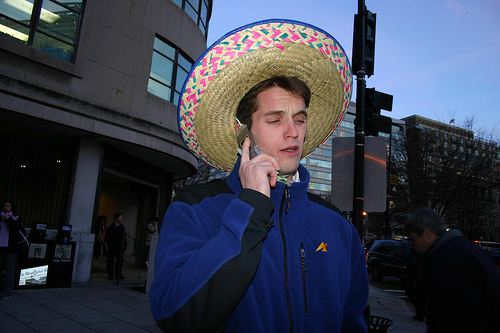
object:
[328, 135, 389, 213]
sign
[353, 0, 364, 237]
post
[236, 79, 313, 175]
man's head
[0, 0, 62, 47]
lights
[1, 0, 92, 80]
window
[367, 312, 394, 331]
bin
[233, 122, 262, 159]
cellphone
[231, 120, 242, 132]
ear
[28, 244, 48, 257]
papers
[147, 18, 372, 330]
man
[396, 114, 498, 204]
building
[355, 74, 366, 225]
sign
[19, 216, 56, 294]
newpaper bin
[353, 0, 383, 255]
traffic light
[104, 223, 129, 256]
jacket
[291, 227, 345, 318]
zipper pocket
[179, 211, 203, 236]
fleece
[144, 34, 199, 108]
window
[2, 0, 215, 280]
building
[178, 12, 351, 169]
hat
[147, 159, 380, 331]
jacket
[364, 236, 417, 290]
vehicle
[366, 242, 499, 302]
street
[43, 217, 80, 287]
newspaper box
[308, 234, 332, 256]
insignia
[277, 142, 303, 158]
mouth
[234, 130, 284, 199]
hand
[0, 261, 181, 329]
side walk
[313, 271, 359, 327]
stripes